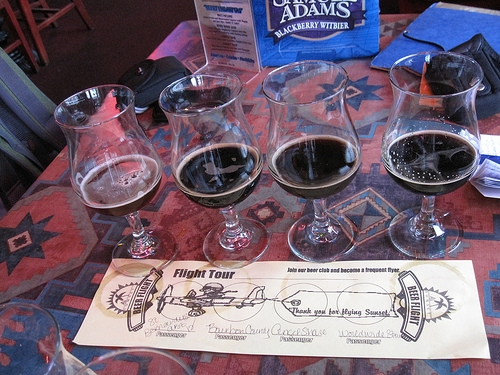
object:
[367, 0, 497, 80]
blue folder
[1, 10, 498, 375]
table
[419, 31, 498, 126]
black case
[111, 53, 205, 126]
black case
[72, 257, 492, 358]
menu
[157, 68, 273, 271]
glass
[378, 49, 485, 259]
glass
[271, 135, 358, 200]
liquid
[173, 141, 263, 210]
liquid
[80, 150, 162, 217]
liquid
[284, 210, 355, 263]
base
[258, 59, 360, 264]
glass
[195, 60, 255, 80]
clear stand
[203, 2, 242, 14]
blue lettering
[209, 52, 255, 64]
blue lettering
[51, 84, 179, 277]
glass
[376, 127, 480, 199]
brown liquid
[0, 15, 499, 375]
glasses/table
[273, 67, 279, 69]
rim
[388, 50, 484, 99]
rim